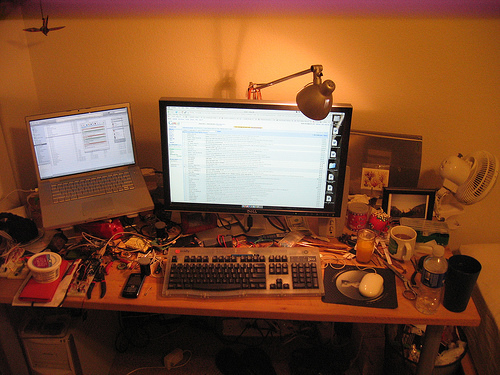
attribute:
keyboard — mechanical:
[156, 240, 333, 303]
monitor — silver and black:
[129, 92, 360, 194]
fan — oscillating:
[438, 155, 468, 193]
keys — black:
[236, 245, 255, 295]